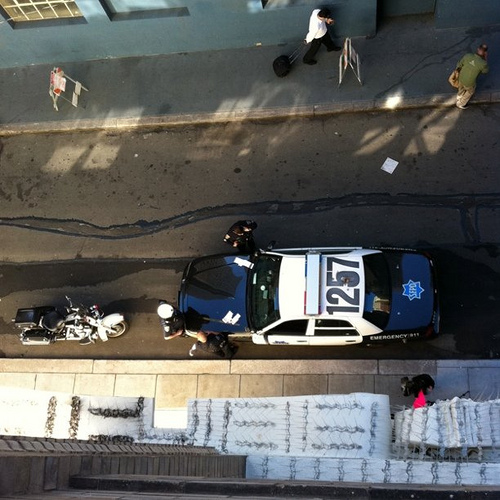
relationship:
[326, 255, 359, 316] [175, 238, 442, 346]
number on police car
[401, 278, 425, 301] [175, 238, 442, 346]
badge on police car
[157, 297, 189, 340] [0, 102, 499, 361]
police officer on street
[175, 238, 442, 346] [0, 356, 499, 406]
police car parked next to sidewalk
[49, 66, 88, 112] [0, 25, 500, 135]
sign on sidewalk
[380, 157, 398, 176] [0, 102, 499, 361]
paper on street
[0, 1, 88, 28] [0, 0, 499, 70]
window on building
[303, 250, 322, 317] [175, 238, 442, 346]
lights on police car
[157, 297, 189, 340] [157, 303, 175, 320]
police officer wearing a helmet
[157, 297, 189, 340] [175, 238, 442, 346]
police officer standing by police car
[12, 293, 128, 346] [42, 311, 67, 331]
motorcycle has a seat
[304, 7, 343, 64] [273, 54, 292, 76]
man pulling bag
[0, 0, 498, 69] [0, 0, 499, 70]
wall of building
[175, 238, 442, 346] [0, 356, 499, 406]
police car near sidewalk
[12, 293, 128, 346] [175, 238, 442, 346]
motorcycle behind police car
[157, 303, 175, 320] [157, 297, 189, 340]
helmet on police officer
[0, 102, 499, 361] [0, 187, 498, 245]
street has a large crack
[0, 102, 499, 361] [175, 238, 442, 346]
street under police car